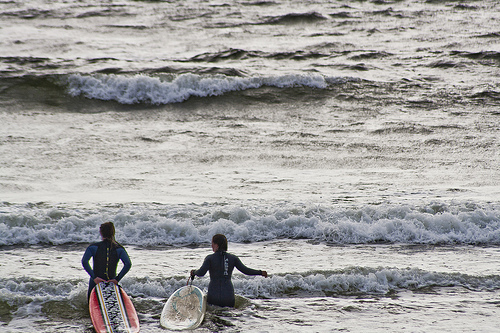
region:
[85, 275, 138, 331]
Red surfboard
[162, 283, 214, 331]
blue and white surfboard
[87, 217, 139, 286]
girl in wetsuit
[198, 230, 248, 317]
second girl in wetsuit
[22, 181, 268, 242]
waves on the landscape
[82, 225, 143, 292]
girl with ponytail in ocean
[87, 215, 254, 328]
2 girls going to surf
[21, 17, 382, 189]
sun is setting over ocean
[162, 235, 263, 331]
girl is dragging surfboard by rope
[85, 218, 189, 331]
girl is holding surfboard behind her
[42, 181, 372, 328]
two surfers in the water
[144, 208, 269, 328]
one surfboard is white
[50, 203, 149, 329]
her surfboard is red with a white and blue stripe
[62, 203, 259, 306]
they both have on wet suits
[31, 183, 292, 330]
both of these surfers are females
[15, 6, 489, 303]
the water is wavey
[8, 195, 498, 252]
there is foam on the waves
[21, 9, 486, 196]
the water has a greyish color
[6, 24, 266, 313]
the water is moving fast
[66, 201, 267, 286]
the surfers are deciding how they are going to surf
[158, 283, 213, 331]
a white surfboard in the water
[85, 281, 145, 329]
a red and white surfboard in the water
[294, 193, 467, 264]
waves in the water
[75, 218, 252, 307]
two surfer girls inwater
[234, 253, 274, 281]
the arm of a surfer girl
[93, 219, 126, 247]
the head of a surfer girl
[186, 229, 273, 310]
a girl wearing a wet suit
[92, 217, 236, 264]
two girls with their hair pulled back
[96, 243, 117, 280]
a zipper on the back of a wetsuit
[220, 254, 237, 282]
a logo on the back of a wet suit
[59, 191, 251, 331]
two people standing in the surf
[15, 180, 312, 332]
waves rolling in to the shore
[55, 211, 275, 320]
two women wearing wet suits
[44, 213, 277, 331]
two women carrying out surf boards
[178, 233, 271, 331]
woman wearing a long sleeve wet suit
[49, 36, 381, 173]
large rolling wave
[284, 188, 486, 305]
splashing white surf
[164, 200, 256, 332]
Woman standing in thigh deep water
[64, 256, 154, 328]
surf board with red details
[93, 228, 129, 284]
yellow detailing on the back of a wet suit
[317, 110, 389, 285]
The water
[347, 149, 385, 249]
The water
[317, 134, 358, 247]
The water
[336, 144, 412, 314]
The water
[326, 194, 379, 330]
The water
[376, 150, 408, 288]
The water